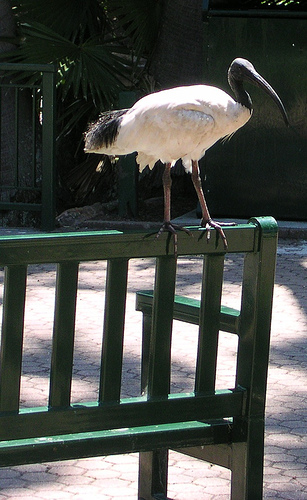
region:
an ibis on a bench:
[74, 49, 293, 257]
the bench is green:
[1, 212, 288, 498]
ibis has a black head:
[223, 52, 294, 132]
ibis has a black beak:
[223, 54, 292, 129]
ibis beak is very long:
[223, 54, 290, 129]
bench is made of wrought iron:
[2, 208, 285, 497]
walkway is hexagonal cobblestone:
[271, 319, 305, 491]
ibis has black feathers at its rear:
[80, 105, 130, 157]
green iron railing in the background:
[1, 55, 60, 230]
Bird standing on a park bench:
[87, 57, 285, 254]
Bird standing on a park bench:
[88, 59, 252, 238]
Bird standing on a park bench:
[79, 45, 288, 245]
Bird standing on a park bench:
[87, 62, 286, 240]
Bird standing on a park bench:
[82, 41, 291, 256]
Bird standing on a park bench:
[80, 60, 286, 259]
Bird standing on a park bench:
[77, 56, 286, 268]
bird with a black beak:
[227, 47, 293, 139]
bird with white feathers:
[127, 90, 236, 156]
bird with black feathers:
[77, 92, 123, 141]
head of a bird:
[224, 52, 266, 90]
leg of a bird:
[157, 166, 190, 255]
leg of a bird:
[189, 158, 215, 227]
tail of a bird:
[92, 113, 143, 159]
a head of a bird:
[220, 53, 258, 83]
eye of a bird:
[233, 63, 245, 74]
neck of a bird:
[229, 78, 250, 99]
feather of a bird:
[86, 97, 130, 140]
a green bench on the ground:
[3, 230, 266, 498]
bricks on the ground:
[39, 463, 273, 499]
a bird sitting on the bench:
[82, 54, 284, 243]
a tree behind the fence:
[15, 8, 159, 200]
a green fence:
[5, 62, 65, 223]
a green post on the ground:
[119, 91, 139, 221]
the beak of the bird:
[254, 78, 287, 125]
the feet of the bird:
[156, 164, 229, 252]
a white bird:
[83, 55, 290, 248]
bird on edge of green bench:
[78, 38, 294, 255]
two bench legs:
[131, 450, 267, 499]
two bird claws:
[141, 210, 242, 256]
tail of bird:
[77, 102, 134, 173]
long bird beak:
[255, 79, 301, 135]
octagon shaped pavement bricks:
[3, 238, 303, 489]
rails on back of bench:
[0, 243, 256, 439]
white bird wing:
[114, 109, 214, 158]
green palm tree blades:
[0, 16, 144, 104]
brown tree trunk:
[148, 4, 212, 91]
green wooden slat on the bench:
[191, 250, 223, 390]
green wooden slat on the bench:
[144, 254, 177, 395]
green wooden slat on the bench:
[94, 257, 125, 400]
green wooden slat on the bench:
[41, 260, 75, 410]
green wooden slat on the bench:
[0, 263, 28, 412]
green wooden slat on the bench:
[0, 384, 238, 442]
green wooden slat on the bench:
[0, 417, 234, 469]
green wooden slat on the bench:
[0, 216, 252, 262]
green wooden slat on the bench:
[141, 254, 177, 403]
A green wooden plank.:
[101, 256, 120, 407]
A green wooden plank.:
[147, 249, 175, 399]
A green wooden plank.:
[202, 245, 217, 394]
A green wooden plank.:
[37, 255, 76, 412]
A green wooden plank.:
[0, 235, 258, 253]